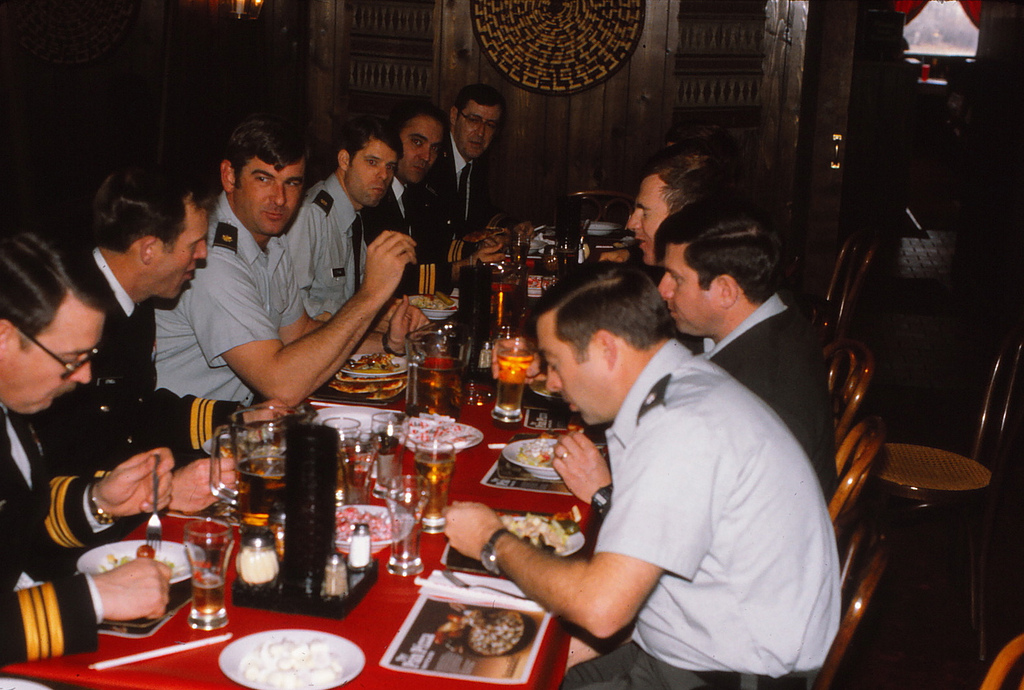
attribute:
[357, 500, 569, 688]
placemat — paper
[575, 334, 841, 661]
shirt — short sleeve